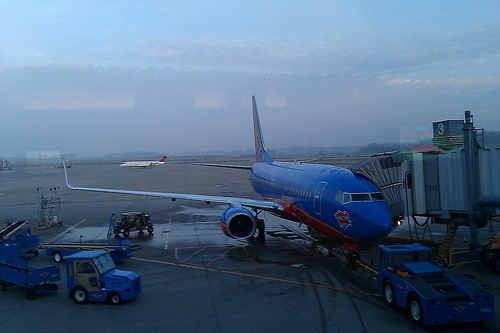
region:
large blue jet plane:
[48, 90, 409, 267]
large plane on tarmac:
[55, 94, 377, 259]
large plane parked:
[45, 97, 400, 260]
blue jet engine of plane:
[218, 205, 256, 237]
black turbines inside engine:
[237, 218, 251, 225]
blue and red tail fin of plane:
[204, 96, 264, 173]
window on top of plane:
[338, 191, 378, 206]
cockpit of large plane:
[325, 168, 394, 240]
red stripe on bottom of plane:
[294, 206, 334, 233]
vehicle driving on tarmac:
[60, 248, 142, 308]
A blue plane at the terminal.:
[204, 93, 393, 264]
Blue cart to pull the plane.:
[366, 247, 470, 312]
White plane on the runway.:
[112, 151, 207, 183]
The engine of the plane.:
[215, 203, 272, 245]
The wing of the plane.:
[53, 162, 278, 223]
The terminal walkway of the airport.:
[366, 146, 491, 210]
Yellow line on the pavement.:
[154, 250, 268, 286]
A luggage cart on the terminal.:
[95, 195, 180, 245]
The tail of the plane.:
[243, 95, 289, 165]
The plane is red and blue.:
[228, 115, 389, 260]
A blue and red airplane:
[59, 92, 398, 272]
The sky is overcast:
[1, 1, 498, 159]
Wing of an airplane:
[58, 154, 284, 247]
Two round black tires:
[68, 283, 127, 309]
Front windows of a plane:
[338, 186, 390, 210]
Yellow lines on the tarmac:
[41, 212, 390, 300]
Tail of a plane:
[244, 89, 281, 168]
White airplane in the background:
[114, 151, 169, 170]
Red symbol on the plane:
[329, 203, 357, 235]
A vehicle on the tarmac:
[108, 207, 158, 244]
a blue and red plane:
[23, 97, 405, 298]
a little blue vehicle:
[27, 234, 157, 309]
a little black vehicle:
[102, 194, 174, 245]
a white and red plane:
[116, 144, 199, 194]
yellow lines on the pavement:
[144, 227, 338, 316]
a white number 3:
[431, 112, 449, 144]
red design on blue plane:
[326, 198, 373, 245]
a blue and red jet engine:
[218, 210, 268, 256]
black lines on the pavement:
[272, 242, 377, 330]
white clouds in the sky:
[60, 34, 499, 136]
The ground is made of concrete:
[153, 276, 364, 331]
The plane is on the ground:
[44, 75, 464, 270]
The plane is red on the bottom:
[267, 194, 356, 247]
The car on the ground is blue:
[349, 232, 496, 327]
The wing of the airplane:
[48, 155, 289, 247]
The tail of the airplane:
[185, 85, 325, 172]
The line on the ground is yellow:
[164, 249, 363, 319]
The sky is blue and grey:
[18, 10, 383, 105]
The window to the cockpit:
[337, 179, 393, 208]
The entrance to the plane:
[347, 108, 498, 225]